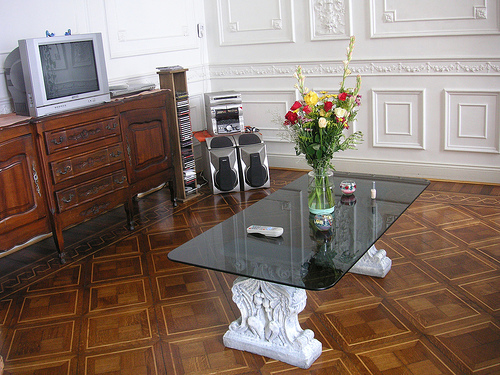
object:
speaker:
[201, 132, 242, 195]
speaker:
[232, 131, 271, 192]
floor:
[0, 165, 500, 375]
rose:
[323, 100, 333, 112]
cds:
[180, 124, 191, 128]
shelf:
[156, 68, 202, 204]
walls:
[474, 3, 499, 15]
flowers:
[333, 106, 347, 118]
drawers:
[48, 140, 128, 184]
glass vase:
[306, 167, 335, 216]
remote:
[246, 224, 284, 237]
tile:
[0, 313, 82, 368]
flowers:
[318, 117, 329, 129]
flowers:
[319, 108, 325, 116]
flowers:
[284, 110, 298, 125]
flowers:
[337, 92, 347, 101]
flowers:
[303, 90, 319, 106]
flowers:
[290, 100, 303, 111]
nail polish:
[370, 181, 376, 200]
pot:
[309, 211, 336, 233]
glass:
[166, 172, 432, 292]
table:
[164, 168, 434, 372]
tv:
[2, 32, 113, 120]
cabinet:
[0, 122, 68, 264]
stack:
[175, 91, 197, 196]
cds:
[180, 137, 193, 142]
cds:
[177, 109, 190, 113]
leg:
[219, 235, 323, 371]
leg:
[314, 201, 393, 280]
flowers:
[354, 97, 361, 107]